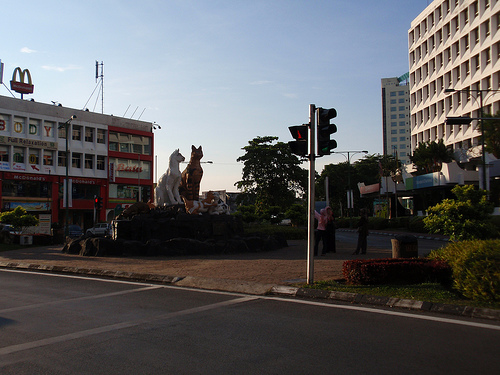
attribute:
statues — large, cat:
[152, 148, 189, 211]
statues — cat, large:
[178, 139, 210, 208]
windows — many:
[390, 89, 409, 149]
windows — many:
[419, 18, 459, 51]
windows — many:
[64, 111, 139, 167]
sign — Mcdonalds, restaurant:
[8, 55, 46, 107]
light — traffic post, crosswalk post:
[289, 123, 311, 147]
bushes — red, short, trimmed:
[344, 257, 453, 287]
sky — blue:
[0, 2, 433, 191]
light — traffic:
[311, 101, 343, 158]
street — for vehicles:
[4, 260, 496, 371]